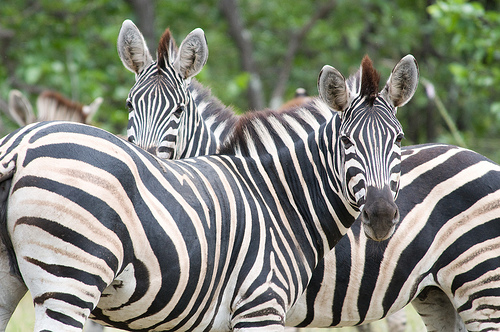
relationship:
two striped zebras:
[1, 21, 498, 329] [2, 20, 499, 331]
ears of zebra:
[116, 20, 211, 84] [112, 20, 225, 160]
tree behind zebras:
[2, 0, 499, 158] [2, 20, 499, 331]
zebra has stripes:
[112, 20, 225, 160] [118, 18, 223, 157]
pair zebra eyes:
[341, 133, 403, 147] [339, 133, 404, 150]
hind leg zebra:
[7, 155, 125, 330] [11, 50, 422, 329]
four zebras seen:
[1, 21, 498, 329] [2, 20, 499, 331]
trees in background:
[2, 0, 499, 158] [1, 2, 500, 150]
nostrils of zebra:
[364, 209, 399, 223] [11, 50, 422, 329]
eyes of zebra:
[339, 133, 404, 150] [11, 50, 422, 329]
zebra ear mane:
[112, 20, 225, 160] [159, 27, 176, 70]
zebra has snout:
[11, 50, 422, 329] [363, 188, 399, 242]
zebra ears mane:
[112, 20, 225, 160] [159, 27, 176, 70]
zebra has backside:
[11, 50, 422, 329] [0, 121, 146, 329]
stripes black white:
[118, 18, 223, 157] [112, 20, 225, 160]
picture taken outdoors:
[0, 1, 499, 329] [3, 2, 500, 331]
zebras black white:
[2, 20, 499, 331] [1, 21, 498, 329]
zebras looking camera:
[2, 20, 499, 331] [0, 1, 499, 329]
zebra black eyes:
[112, 20, 225, 160] [126, 95, 186, 117]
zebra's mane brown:
[112, 20, 225, 160] [159, 27, 176, 70]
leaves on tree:
[2, 0, 499, 158] [221, 7, 484, 153]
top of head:
[317, 53, 420, 109] [4, 86, 111, 128]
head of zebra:
[4, 86, 111, 128] [5, 86, 131, 138]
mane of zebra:
[35, 87, 86, 122] [11, 50, 422, 329]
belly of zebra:
[98, 266, 240, 329] [11, 50, 422, 329]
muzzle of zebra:
[363, 188, 399, 242] [11, 50, 422, 329]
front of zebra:
[159, 27, 176, 70] [11, 50, 422, 329]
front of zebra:
[159, 27, 176, 70] [114, 17, 499, 332]